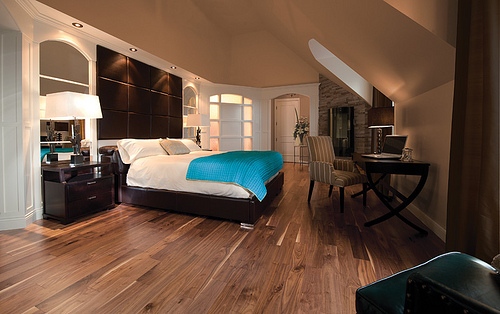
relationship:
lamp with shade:
[43, 90, 105, 163] [42, 92, 103, 122]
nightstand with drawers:
[41, 157, 120, 228] [68, 177, 117, 218]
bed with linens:
[98, 132, 289, 222] [117, 131, 285, 198]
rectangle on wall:
[94, 47, 133, 86] [6, 1, 213, 221]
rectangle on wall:
[99, 110, 130, 142] [6, 1, 213, 221]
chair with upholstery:
[293, 128, 365, 208] [303, 133, 361, 192]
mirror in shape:
[41, 35, 93, 170] [36, 44, 97, 155]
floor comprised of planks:
[8, 150, 440, 308] [4, 144, 440, 306]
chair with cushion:
[293, 128, 365, 208] [317, 157, 351, 179]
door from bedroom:
[275, 99, 301, 161] [1, 2, 499, 308]